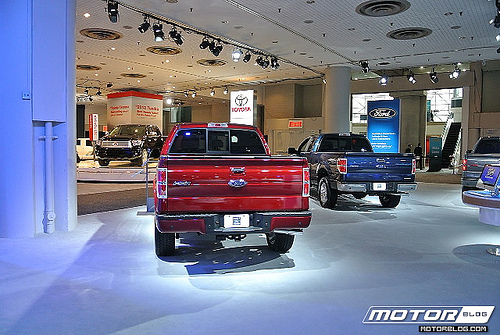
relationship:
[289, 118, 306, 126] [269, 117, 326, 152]
sign on wall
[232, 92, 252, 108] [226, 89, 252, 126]
logo on wall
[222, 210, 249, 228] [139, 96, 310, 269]
licenseplate on truck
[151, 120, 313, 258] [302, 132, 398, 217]
truck next to truck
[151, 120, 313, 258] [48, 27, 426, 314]
truck in showroom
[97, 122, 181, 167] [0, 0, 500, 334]
truck in room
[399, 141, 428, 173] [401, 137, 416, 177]
men standing by man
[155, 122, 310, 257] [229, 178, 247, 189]
truck has symbol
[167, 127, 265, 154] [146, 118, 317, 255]
window of a truck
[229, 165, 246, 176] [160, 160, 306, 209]
handle pulls down gate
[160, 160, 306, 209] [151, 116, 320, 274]
gate on truck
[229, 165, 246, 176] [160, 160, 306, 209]
handle on gate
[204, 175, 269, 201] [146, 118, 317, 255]
symbol on truck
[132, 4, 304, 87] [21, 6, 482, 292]
lights in showroom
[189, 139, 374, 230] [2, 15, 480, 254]
cars in showcase